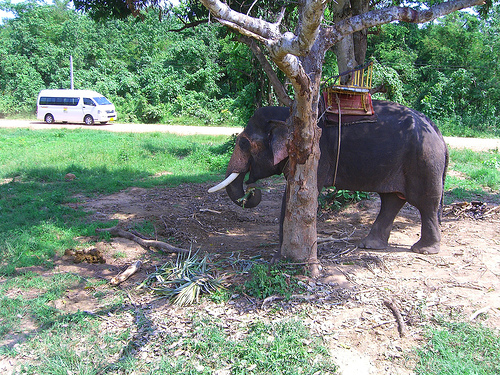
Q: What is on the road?
A: Van.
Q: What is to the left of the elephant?
A: A tree.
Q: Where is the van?
A: On a road.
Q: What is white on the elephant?
A: Its tusks.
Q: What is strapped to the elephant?
A: A saddle.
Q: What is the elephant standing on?
A: Dirt.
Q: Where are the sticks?
A: All over the dirt.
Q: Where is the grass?
A: To the right of the van.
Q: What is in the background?
A: Trees and bushes.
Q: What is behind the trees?
A: The sky.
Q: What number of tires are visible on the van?
A: Two.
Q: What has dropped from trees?
A: Sticks and leaves.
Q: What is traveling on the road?
A: Tour bus.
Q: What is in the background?
A: Trees and shrubs.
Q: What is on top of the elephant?
A: A seat.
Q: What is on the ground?
A: Grass and sand.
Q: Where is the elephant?
A: In the trees.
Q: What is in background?
A: Dirt road.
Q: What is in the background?
A: Trees.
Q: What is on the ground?
A: Grass.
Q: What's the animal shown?
A: Elephant.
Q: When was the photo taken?
A: Daytime.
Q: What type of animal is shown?
A: Elephant.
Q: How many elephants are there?
A: One.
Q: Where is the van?
A: Road.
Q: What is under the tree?
A: Elephant.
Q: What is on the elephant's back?
A: Seat.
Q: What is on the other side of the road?
A: Trees.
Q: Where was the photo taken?
A: On a back road.